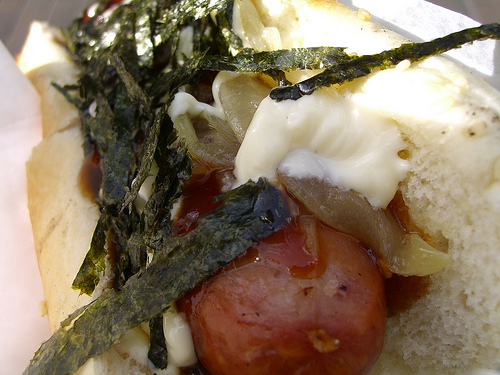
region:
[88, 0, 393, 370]
toppings on a hotdog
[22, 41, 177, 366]
white bread under a hotdog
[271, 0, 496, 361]
part of a white hotdog bun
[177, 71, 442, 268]
cooked onions on a hotdog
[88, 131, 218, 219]
brown sauce on a hotdog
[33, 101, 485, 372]
a hotdog on a bun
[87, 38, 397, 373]
a hotdog with green toppings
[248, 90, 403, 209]
mayo on a hotdog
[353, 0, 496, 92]
part of a napkin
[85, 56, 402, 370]
a mixure of toppings on a hotdog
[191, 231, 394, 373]
A hot dog poking through the bun.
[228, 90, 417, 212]
A white creamy sauce over the hotdog.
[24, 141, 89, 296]
The bread of the hot dog bun.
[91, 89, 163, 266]
A dried green object on the hot dog.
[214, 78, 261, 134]
An onion atop the hot dog.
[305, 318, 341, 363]
The end portion of the hot dog, with a slight hole.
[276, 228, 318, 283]
Juice dripping over the hot dog.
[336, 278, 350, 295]
A black speck on the hot dog.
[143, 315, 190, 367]
Cream and green stuff meet next to the hot dog.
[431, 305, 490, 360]
A close up of the inside of the bread.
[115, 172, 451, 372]
SMOKED SAUSAGE IN BREADN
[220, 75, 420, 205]
MAYONAISE USED AS CONDIMENT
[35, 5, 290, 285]
DARK GREEN LEAFY RELISH ON SAUSAGE DOG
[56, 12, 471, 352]
BREAD IS A HOTDOG BUN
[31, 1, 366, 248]
GREEN LEAFY VEGETABLE IS SPINACH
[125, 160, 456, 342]
CATSUP IS ON SMOKED SAUSAGE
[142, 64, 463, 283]
DILL PICKLE ON SMOKED SAUSAGE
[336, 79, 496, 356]
HOT DOG BUN IS MADE FROM WHITE BREAD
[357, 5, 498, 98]
FOOD IS ON WHITE DISH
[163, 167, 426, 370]
SMOKED SAUSAGE COOKED ON GRILL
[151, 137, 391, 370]
plump juicy hot dog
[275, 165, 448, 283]
sauteed white onion on hot dog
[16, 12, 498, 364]
white bread hot dog bun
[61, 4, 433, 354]
condiments on top of hot dog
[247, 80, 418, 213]
mayo on top of hot dog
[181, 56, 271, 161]
sauteed onion on top of hot dog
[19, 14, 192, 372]
toasted side of hot dog bun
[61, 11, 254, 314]
green vegetables on top of hot dog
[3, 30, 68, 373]
wrapper around hot dog bun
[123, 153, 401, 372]
plump hot dog on bun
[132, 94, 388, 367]
hot dog between bread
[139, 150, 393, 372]
hot dog is red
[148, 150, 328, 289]
sauce on top of hotdog.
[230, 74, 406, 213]
mayonnaise on top of hotdog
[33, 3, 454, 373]
vegetable on hotdog is green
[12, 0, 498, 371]
vegetable on top of hot dog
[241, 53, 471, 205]
mayonnaise is white in color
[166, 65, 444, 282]
onions on top of hot dog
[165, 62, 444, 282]
onions are cooked and clear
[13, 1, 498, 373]
bread holding meat and vegetables